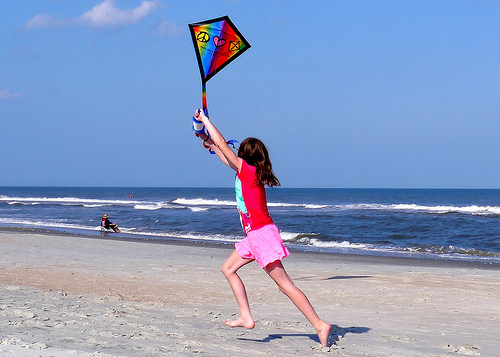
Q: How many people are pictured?
A: Two.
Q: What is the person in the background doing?
A: Sitting in a chair.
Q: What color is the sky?
A: Blue.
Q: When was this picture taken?
A: During the day.